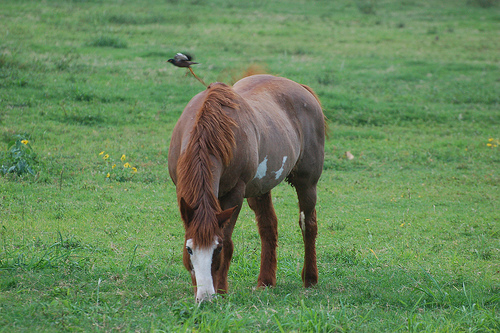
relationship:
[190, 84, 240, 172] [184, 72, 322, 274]
mane of horse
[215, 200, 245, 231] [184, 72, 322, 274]
ear of horse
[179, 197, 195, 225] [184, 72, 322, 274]
ears of horse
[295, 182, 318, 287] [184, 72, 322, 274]
legs of horse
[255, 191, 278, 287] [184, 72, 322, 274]
leg of horse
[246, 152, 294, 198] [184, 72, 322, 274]
stomach of horse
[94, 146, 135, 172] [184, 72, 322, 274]
flowers near horse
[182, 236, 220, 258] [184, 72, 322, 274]
eyes of horse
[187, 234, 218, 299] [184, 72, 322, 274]
face of horse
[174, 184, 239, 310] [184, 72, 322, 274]
head of horse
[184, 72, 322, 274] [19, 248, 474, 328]
horse eating grass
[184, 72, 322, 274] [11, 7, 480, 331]
horse in meadow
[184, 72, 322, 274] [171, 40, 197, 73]
horse and bird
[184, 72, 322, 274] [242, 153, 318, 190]
horse has spots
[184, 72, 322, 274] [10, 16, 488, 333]
horse in field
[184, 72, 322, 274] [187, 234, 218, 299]
horse with face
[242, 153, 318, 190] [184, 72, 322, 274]
spots on horse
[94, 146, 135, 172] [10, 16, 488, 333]
flowers in field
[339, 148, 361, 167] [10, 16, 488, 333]
rock in field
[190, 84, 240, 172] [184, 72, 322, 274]
mane on horse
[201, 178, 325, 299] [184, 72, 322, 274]
legs of horse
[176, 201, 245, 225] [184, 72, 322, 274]
ears of horse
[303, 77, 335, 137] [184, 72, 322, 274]
tail of horse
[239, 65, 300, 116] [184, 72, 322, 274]
back of horse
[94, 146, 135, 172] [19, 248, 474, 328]
flowers in grass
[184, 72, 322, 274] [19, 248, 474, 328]
horse in grass